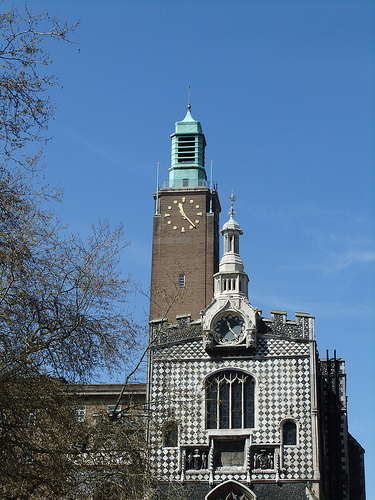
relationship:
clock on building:
[164, 195, 204, 232] [147, 82, 220, 322]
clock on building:
[215, 312, 245, 343] [147, 191, 366, 499]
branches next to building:
[1, 0, 191, 499] [147, 191, 366, 499]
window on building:
[205, 368, 257, 430] [147, 191, 366, 499]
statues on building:
[185, 447, 208, 468] [147, 191, 366, 499]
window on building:
[177, 270, 189, 289] [147, 82, 220, 322]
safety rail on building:
[162, 177, 217, 191] [147, 82, 220, 322]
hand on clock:
[229, 328, 239, 338] [215, 312, 245, 343]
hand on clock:
[224, 321, 232, 330] [215, 312, 245, 343]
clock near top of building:
[164, 195, 204, 232] [147, 82, 220, 322]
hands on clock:
[175, 201, 197, 229] [164, 195, 204, 232]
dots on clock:
[165, 197, 181, 211] [164, 195, 204, 232]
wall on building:
[148, 338, 314, 480] [147, 191, 366, 499]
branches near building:
[1, 0, 191, 499] [147, 82, 220, 322]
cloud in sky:
[258, 295, 372, 322] [3, 3, 375, 399]